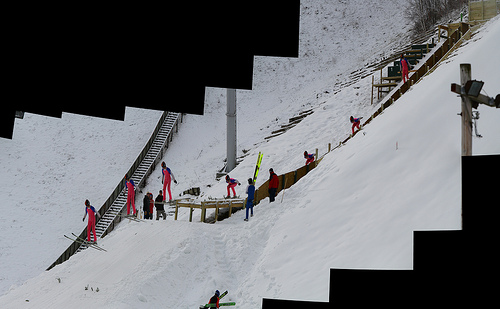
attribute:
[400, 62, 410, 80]
ski outfit — red, black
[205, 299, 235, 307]
ski — green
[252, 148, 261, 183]
skis — yellow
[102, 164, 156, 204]
person — black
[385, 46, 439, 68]
outfi — red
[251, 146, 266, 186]
banner — green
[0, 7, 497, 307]
mountain — snow covered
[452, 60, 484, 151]
pole — wooden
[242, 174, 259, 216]
person — standing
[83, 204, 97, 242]
suit — red, black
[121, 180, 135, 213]
suit — red, black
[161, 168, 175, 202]
suit — red, black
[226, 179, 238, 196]
suit — red, black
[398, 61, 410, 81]
suit — red, black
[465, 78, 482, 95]
object — black